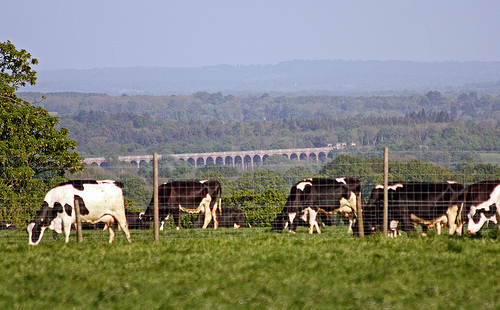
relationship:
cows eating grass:
[26, 178, 499, 246] [3, 217, 498, 309]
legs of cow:
[105, 214, 131, 246] [27, 179, 139, 245]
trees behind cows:
[84, 157, 493, 210] [26, 178, 499, 246]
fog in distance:
[1, 0, 499, 61] [1, 0, 498, 98]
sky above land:
[1, 0, 499, 61] [0, 61, 499, 309]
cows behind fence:
[26, 178, 499, 246] [0, 161, 499, 237]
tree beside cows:
[0, 41, 89, 229] [26, 178, 499, 246]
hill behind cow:
[27, 92, 489, 156] [139, 176, 225, 235]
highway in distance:
[76, 144, 343, 168] [27, 92, 489, 156]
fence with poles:
[0, 161, 499, 237] [146, 147, 393, 252]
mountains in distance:
[23, 54, 493, 97] [1, 0, 498, 98]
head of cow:
[27, 219, 48, 246] [27, 179, 139, 245]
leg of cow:
[169, 196, 179, 230] [139, 176, 225, 235]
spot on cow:
[72, 196, 91, 215] [27, 179, 139, 245]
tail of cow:
[214, 180, 224, 217] [139, 176, 225, 235]